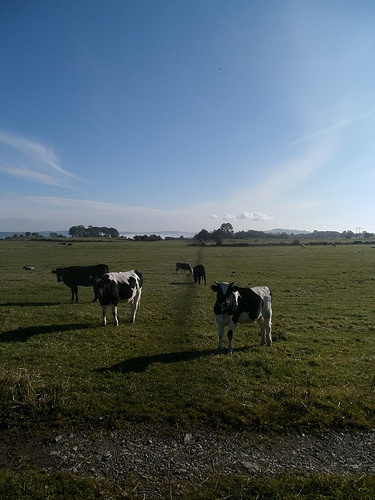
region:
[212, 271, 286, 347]
Cow looking at the camera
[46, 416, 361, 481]
Dirt path in middle of grass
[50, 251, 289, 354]
Five cows standing in the grass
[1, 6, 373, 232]
Sky with different shades of blue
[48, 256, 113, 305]
Completely black cow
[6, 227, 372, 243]
Row of trees far behind cows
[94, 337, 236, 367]
Cow's shadow on the ground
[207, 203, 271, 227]
Single white fluffy cloud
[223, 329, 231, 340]
Black spot on cow's leg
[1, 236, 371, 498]
A large grassy field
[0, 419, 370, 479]
A rocky path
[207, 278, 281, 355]
A cow in a field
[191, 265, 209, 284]
A cow in a field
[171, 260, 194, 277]
A cow in a field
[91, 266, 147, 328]
A cow in a field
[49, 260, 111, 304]
A cow in a field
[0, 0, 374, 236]
A clear blue sky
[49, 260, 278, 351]
some cows in a field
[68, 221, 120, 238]
a group of trees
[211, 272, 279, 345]
this is a cow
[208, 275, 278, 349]
the cow is staring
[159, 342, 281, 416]
this is the grass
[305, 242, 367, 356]
the grass is short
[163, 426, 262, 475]
this is the stones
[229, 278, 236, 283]
this is the horn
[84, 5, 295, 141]
this is the sky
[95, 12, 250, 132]
the sky is clear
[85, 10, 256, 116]
the sky is blue in color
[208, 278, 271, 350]
A bull standing in a field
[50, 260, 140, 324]
Two bulls standing in a field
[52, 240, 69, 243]
Bovine in the distance standing in a field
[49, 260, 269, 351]
Five bulls standing in a field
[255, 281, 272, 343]
Hind legs on a bull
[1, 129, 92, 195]
Wispy clouds in the blue sky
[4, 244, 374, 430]
A large field of green grass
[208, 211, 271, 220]
Fluffy clouds in the sky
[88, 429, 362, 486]
this is a path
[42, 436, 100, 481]
these are rocks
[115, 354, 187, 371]
this is va shadow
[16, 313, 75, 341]
this is a shadow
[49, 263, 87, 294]
this is a cow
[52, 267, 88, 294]
this is a black cow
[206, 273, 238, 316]
this is a head of a cow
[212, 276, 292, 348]
this is a white and black cow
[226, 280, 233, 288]
this is a horn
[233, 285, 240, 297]
this is an ear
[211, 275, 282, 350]
A cow in a field.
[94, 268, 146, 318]
A cow in a field.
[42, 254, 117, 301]
A cow in a field.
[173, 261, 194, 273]
A cow in a field.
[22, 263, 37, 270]
A cow in a field.